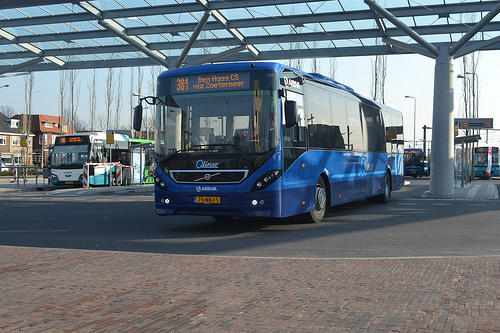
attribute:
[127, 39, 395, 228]
bus — blue, green, glass, parked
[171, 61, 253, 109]
sign — yellow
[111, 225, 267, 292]
pavement — street, brick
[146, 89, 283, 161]
windshield — large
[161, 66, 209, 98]
number — 381, orange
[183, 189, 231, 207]
plate — orange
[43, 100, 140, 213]
bus — white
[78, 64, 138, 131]
tree — skinny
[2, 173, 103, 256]
sidewalk — brick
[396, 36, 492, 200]
column — holding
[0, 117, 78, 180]
house — parked